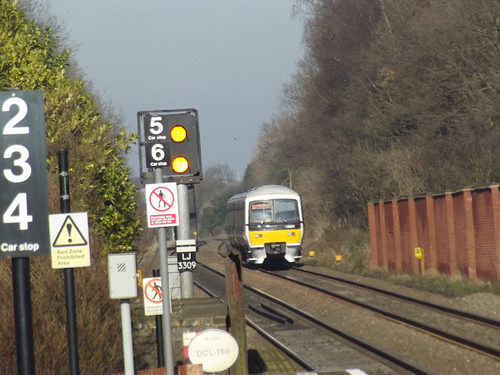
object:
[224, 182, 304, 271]
train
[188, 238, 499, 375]
tracks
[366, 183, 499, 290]
wall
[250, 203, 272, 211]
electric sign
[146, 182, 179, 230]
sign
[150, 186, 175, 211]
no walking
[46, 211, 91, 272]
sign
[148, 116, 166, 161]
56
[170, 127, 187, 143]
light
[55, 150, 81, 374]
black pole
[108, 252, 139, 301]
box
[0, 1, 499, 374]
trees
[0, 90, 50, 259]
234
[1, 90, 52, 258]
sign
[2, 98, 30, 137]
2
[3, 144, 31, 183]
3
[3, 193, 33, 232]
4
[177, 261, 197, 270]
3309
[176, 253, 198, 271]
sign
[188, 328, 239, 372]
sign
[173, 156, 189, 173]
light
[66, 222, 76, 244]
exclamation point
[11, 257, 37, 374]
black pole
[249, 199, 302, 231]
windshield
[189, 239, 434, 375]
track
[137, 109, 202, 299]
post